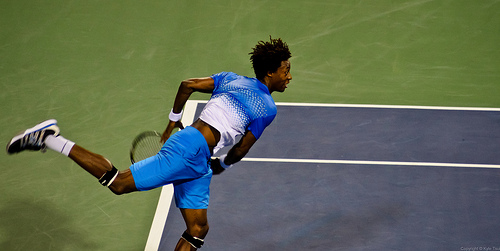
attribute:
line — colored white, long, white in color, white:
[135, 98, 197, 250]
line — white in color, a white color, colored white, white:
[239, 152, 500, 175]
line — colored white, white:
[276, 99, 500, 114]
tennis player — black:
[5, 34, 299, 250]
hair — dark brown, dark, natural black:
[252, 37, 293, 82]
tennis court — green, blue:
[144, 98, 500, 237]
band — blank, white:
[98, 162, 120, 189]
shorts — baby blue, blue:
[131, 126, 211, 209]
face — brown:
[277, 59, 294, 92]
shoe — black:
[8, 115, 64, 155]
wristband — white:
[169, 107, 183, 119]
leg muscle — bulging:
[83, 145, 113, 175]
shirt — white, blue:
[200, 73, 276, 156]